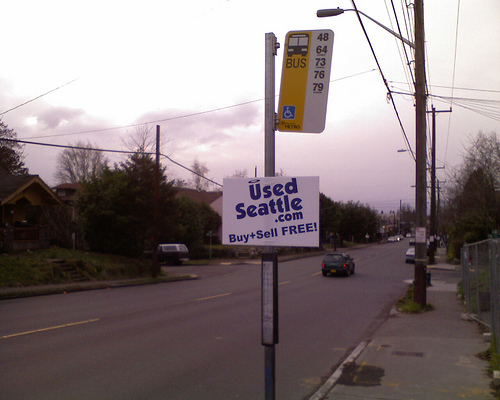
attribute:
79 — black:
[304, 80, 326, 94]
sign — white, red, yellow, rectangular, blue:
[206, 163, 329, 272]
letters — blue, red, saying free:
[248, 182, 306, 210]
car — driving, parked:
[320, 246, 360, 287]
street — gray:
[183, 336, 240, 369]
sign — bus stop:
[282, 19, 338, 145]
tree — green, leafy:
[87, 178, 170, 224]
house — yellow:
[9, 173, 89, 260]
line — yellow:
[20, 309, 112, 338]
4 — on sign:
[315, 31, 324, 43]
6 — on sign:
[312, 44, 325, 59]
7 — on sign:
[311, 55, 321, 69]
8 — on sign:
[324, 34, 332, 41]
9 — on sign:
[318, 81, 328, 93]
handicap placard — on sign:
[277, 101, 302, 123]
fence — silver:
[463, 246, 496, 313]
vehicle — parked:
[150, 229, 194, 273]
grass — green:
[56, 250, 97, 257]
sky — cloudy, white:
[92, 68, 205, 125]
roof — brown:
[4, 166, 30, 186]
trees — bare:
[73, 147, 203, 236]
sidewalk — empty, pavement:
[391, 331, 472, 394]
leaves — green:
[130, 186, 147, 191]